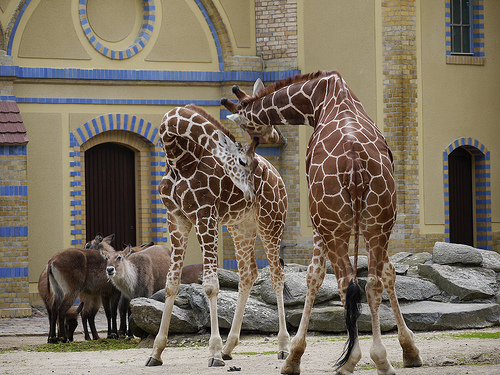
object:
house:
[0, 0, 500, 320]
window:
[449, 0, 475, 57]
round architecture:
[76, 2, 159, 61]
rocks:
[389, 298, 500, 334]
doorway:
[74, 128, 158, 269]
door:
[79, 141, 141, 256]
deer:
[36, 229, 117, 344]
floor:
[0, 299, 500, 375]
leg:
[319, 229, 362, 374]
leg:
[359, 238, 396, 374]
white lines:
[335, 155, 340, 176]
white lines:
[187, 184, 210, 194]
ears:
[225, 112, 244, 128]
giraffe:
[219, 57, 431, 375]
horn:
[219, 96, 239, 117]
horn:
[229, 83, 249, 102]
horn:
[240, 134, 260, 158]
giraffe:
[141, 100, 295, 369]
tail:
[329, 180, 367, 373]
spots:
[309, 162, 325, 188]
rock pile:
[126, 241, 500, 341]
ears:
[121, 243, 132, 256]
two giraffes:
[143, 65, 439, 375]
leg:
[139, 225, 187, 368]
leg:
[192, 214, 232, 369]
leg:
[221, 221, 264, 362]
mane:
[238, 69, 336, 108]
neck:
[248, 76, 323, 128]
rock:
[125, 292, 194, 341]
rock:
[185, 277, 285, 337]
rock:
[196, 263, 244, 288]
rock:
[259, 267, 340, 307]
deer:
[99, 242, 175, 337]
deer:
[46, 240, 157, 344]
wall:
[0, 140, 30, 318]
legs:
[257, 210, 293, 363]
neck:
[161, 104, 233, 159]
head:
[214, 129, 262, 207]